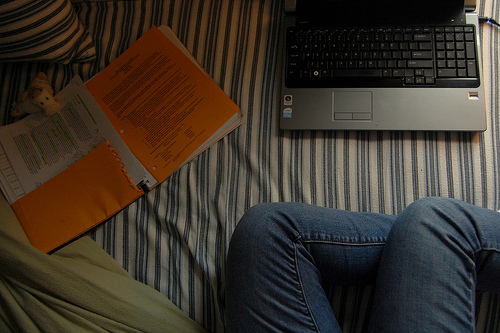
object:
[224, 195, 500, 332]
legs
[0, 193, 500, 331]
person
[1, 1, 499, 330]
sheet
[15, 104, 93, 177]
text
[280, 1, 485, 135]
laptop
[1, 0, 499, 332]
bed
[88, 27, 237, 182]
paper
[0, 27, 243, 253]
folder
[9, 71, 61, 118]
stuff cow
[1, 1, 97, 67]
pillow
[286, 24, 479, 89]
keyboard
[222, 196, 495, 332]
jeans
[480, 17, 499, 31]
cable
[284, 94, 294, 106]
sticker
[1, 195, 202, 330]
blanket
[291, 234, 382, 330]
inseam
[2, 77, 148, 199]
papers